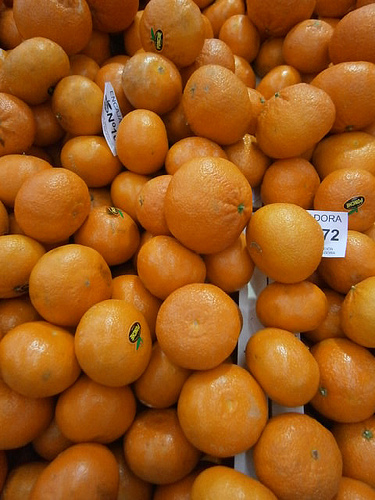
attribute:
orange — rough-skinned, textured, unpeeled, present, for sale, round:
[182, 64, 250, 147]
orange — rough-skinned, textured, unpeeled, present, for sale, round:
[255, 83, 335, 158]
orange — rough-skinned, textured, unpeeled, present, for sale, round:
[13, 167, 91, 240]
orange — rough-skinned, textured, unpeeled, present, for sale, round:
[166, 157, 253, 254]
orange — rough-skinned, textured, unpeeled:
[314, 167, 375, 232]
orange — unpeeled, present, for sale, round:
[140, 1, 204, 69]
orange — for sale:
[74, 298, 152, 387]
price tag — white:
[101, 81, 124, 159]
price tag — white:
[307, 210, 348, 259]